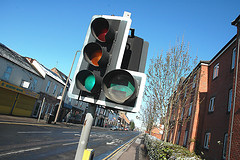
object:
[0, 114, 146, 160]
block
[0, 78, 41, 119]
building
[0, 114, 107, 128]
pavement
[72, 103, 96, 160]
pole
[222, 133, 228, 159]
window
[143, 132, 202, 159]
bushes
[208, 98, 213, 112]
window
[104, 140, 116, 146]
arrow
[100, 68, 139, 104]
signal light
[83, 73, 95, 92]
light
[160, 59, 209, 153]
building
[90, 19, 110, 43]
light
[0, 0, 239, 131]
blue sky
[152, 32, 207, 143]
trees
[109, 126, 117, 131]
cars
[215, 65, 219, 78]
window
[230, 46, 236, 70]
window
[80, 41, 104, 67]
signal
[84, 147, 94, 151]
button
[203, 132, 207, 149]
window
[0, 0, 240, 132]
clouds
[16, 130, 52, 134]
lines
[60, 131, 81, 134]
lines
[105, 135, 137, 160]
lines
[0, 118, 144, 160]
street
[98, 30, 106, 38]
red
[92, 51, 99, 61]
yellow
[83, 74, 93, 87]
green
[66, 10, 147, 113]
traffic signal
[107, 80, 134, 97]
arrow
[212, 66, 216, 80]
window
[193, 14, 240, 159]
building